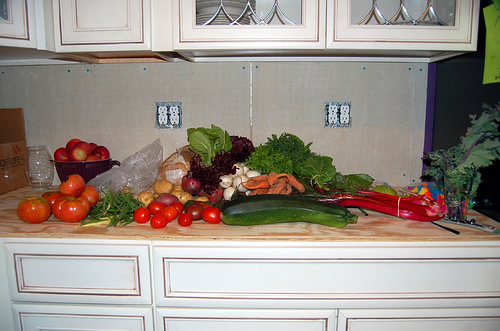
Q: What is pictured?
A: Vegetables.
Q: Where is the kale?
A: Far right.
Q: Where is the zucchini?
A: Front.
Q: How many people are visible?
A: Zero.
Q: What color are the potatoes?
A: White and red.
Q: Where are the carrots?
A: In the middle.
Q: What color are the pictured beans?
A: Green.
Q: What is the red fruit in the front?
A: Tomato.